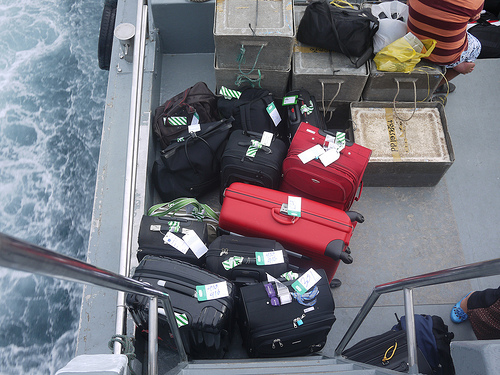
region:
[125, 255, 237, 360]
a piece of black luggage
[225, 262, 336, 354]
a piece of black luggage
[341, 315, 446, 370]
a piece of black luggage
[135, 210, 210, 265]
a piece of black luggage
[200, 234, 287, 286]
a piece of black luggage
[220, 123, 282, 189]
a piece of black luggage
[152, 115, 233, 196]
a piece of black luggage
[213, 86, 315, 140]
a piece of black luggage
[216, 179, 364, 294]
a piece of red luggage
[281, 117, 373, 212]
a piece of red luggage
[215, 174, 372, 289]
red suitcase on it's side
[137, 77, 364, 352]
luggage at the bottom of the stairs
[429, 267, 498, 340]
foot of girl standing by luggage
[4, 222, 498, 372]
silver railings on both side of the stairs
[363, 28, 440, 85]
a yellow sheer bag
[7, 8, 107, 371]
choppy water on the side of the boat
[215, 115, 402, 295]
two red luggage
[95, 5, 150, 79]
cup sitting on side of boat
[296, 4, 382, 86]
a black bag behing woman sitting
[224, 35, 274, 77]
green rope handle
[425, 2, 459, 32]
part of person's striped shirt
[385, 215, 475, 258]
part of the floor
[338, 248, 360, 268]
a wheel on luggage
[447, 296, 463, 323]
a blue shoe on foot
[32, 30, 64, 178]
portion of water near luggage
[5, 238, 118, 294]
railing by the stairs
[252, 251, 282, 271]
blue and white luggage tag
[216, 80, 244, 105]
red and white striped tag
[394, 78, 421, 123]
strap on gray container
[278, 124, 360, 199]
piece of red luggage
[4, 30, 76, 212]
The water is white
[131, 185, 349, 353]
The suit cases are lined up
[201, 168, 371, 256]
the suit case is red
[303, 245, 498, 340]
The bars are metal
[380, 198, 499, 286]
The floor is gray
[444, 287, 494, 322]
The shoes are blue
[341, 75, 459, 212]
The box is square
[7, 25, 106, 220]
The water is rough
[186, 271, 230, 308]
The suit case has a tag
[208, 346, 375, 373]
The stairs are gray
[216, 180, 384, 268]
a hard red suitcase on a boat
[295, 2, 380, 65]
a black bag on a boat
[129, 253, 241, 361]
a hard black suitcase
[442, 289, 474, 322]
a blue shoe on a woman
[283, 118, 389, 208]
a red suitcase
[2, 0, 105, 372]
water outside a boat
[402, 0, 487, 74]
a red and pink striped shirt on a person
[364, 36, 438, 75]
a yellow plastic bag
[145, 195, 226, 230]
a green bag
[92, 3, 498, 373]
a boat on the water